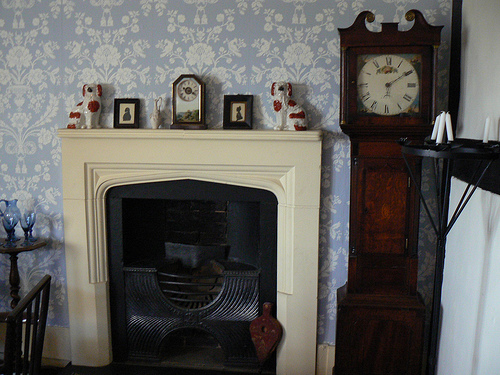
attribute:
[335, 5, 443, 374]
clock — wooden, white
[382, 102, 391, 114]
numerial — black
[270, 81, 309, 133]
figurine — dog, seated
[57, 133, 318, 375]
fireplace — metal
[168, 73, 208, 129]
clcok — small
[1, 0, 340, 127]
wall — blue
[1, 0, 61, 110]
pattern — white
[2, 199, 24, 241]
vase — glass, blue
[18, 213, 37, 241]
cup — blue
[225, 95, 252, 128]
picture — framed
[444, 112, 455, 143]
candle — white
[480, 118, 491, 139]
candle — whtie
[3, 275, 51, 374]
chair — black